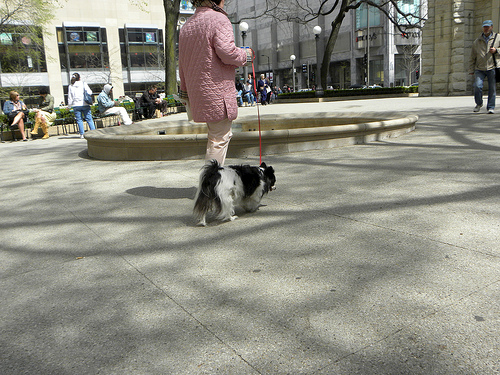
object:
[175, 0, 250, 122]
coat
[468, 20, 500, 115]
man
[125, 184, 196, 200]
shadow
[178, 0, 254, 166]
person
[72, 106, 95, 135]
jeans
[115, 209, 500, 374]
slab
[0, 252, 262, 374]
slab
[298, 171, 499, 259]
slab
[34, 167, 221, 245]
slab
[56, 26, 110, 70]
window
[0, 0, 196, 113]
building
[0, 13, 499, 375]
park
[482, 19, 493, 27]
ball cap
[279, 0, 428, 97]
tree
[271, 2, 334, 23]
branches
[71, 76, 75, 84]
ponytail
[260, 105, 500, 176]
shadow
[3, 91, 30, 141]
women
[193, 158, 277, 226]
dog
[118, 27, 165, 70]
window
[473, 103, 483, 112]
shoes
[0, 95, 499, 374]
ground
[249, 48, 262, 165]
leash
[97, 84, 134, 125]
person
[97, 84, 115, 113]
hoodie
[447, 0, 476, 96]
column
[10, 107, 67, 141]
bench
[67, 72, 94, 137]
woman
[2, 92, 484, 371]
sun